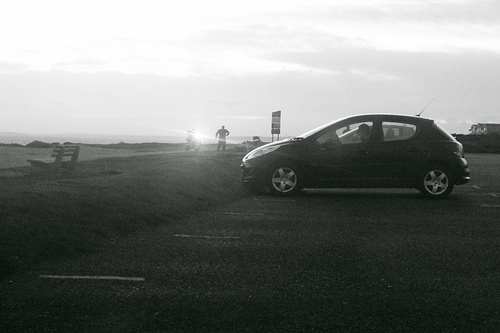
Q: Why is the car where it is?
A: It's parked.